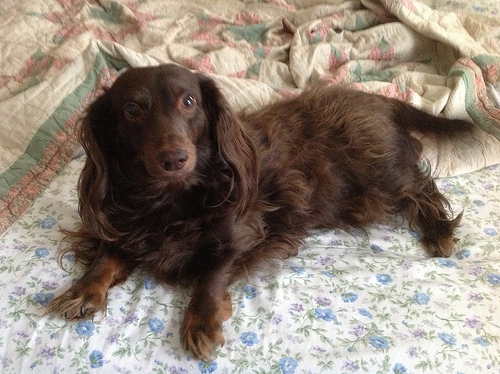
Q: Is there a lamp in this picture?
A: No, there are no lamps.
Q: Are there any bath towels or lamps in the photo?
A: No, there are no lamps or bath towels.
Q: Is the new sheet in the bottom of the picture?
A: Yes, the bed sheet is in the bottom of the image.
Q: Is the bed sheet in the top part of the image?
A: No, the bed sheet is in the bottom of the image.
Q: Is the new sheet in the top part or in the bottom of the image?
A: The sheet is in the bottom of the image.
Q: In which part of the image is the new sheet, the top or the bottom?
A: The sheet is in the bottom of the image.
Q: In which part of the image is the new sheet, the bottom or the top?
A: The sheet is in the bottom of the image.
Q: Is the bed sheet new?
A: Yes, the bed sheet is new.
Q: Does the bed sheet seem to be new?
A: Yes, the bed sheet is new.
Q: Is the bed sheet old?
A: No, the bed sheet is new.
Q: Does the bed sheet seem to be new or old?
A: The bed sheet is new.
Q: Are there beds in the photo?
A: Yes, there is a bed.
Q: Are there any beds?
A: Yes, there is a bed.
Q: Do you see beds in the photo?
A: Yes, there is a bed.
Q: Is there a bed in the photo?
A: Yes, there is a bed.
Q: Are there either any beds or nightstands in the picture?
A: Yes, there is a bed.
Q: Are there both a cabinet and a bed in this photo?
A: No, there is a bed but no cabinets.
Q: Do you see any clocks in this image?
A: No, there are no clocks.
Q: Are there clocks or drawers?
A: No, there are no clocks or drawers.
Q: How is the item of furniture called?
A: The piece of furniture is a bed.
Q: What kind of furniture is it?
A: The piece of furniture is a bed.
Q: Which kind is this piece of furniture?
A: This is a bed.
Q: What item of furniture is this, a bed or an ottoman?
A: This is a bed.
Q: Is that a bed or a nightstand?
A: That is a bed.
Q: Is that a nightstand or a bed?
A: That is a bed.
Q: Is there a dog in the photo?
A: Yes, there is a dog.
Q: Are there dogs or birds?
A: Yes, there is a dog.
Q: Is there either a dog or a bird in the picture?
A: Yes, there is a dog.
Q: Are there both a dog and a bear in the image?
A: No, there is a dog but no bears.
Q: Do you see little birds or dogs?
A: Yes, there is a little dog.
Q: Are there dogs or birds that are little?
A: Yes, the dog is little.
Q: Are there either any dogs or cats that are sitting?
A: Yes, the dog is sitting.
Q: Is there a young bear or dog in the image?
A: Yes, there is a young dog.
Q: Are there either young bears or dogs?
A: Yes, there is a young dog.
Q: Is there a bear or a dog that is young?
A: Yes, the dog is young.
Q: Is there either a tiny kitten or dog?
A: Yes, there is a tiny dog.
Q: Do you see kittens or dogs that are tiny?
A: Yes, the dog is tiny.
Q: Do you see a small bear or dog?
A: Yes, there is a small dog.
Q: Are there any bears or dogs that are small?
A: Yes, the dog is small.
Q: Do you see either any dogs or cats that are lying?
A: Yes, the dog is lying.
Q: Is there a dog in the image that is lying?
A: Yes, there is a dog that is lying.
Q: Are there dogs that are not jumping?
A: Yes, there is a dog that is lying.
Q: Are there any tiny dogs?
A: Yes, there is a tiny dog.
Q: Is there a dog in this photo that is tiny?
A: Yes, there is a dog that is tiny.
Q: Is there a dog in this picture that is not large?
A: Yes, there is a tiny dog.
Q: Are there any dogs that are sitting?
A: Yes, there is a dog that is sitting.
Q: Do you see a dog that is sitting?
A: Yes, there is a dog that is sitting.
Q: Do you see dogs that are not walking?
A: Yes, there is a dog that is sitting .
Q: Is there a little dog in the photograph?
A: Yes, there is a little dog.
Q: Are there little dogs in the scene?
A: Yes, there is a little dog.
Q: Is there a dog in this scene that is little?
A: Yes, there is a dog that is little.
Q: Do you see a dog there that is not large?
A: Yes, there is a little dog.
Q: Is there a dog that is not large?
A: Yes, there is a little dog.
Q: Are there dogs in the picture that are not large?
A: Yes, there is a little dog.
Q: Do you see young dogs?
A: Yes, there is a young dog.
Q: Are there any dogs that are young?
A: Yes, there is a dog that is young.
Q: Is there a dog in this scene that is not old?
A: Yes, there is an young dog.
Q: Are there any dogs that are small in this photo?
A: Yes, there is a small dog.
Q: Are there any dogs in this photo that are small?
A: Yes, there is a dog that is small.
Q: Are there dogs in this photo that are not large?
A: Yes, there is a small dog.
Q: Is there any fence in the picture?
A: No, there are no fences.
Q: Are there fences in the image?
A: No, there are no fences.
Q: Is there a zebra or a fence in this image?
A: No, there are no fences or zebras.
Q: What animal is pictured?
A: The animal is a dog.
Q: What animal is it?
A: The animal is a dog.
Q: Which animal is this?
A: This is a dog.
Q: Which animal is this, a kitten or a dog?
A: This is a dog.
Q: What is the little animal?
A: The animal is a dog.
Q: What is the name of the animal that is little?
A: The animal is a dog.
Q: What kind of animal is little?
A: The animal is a dog.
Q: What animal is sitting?
A: The animal is a dog.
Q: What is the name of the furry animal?
A: The animal is a dog.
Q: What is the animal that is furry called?
A: The animal is a dog.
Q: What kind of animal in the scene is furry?
A: The animal is a dog.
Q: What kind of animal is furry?
A: The animal is a dog.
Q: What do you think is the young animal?
A: The animal is a dog.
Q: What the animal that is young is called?
A: The animal is a dog.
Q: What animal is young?
A: The animal is a dog.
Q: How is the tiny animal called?
A: The animal is a dog.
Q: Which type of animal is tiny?
A: The animal is a dog.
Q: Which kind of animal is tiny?
A: The animal is a dog.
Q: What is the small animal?
A: The animal is a dog.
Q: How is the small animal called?
A: The animal is a dog.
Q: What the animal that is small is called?
A: The animal is a dog.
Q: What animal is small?
A: The animal is a dog.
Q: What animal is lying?
A: The animal is a dog.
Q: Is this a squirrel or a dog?
A: This is a dog.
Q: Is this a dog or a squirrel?
A: This is a dog.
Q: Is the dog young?
A: Yes, the dog is young.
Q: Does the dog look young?
A: Yes, the dog is young.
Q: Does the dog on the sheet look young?
A: Yes, the dog is young.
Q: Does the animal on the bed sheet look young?
A: Yes, the dog is young.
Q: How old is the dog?
A: The dog is young.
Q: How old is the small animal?
A: The dog is young.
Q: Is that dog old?
A: No, the dog is young.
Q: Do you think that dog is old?
A: No, the dog is young.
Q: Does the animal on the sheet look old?
A: No, the dog is young.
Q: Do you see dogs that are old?
A: No, there is a dog but it is young.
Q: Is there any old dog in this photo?
A: No, there is a dog but it is young.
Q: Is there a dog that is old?
A: No, there is a dog but it is young.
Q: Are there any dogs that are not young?
A: No, there is a dog but it is young.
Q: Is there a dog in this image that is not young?
A: No, there is a dog but it is young.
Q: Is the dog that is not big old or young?
A: The dog is young.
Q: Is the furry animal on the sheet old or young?
A: The dog is young.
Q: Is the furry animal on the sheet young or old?
A: The dog is young.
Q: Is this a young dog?
A: Yes, this is a young dog.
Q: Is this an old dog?
A: No, this is a young dog.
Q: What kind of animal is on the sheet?
A: The animal is a dog.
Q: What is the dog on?
A: The dog is on the sheet.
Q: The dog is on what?
A: The dog is on the sheet.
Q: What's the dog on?
A: The dog is on the sheet.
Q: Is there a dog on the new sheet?
A: Yes, there is a dog on the sheet.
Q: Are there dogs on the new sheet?
A: Yes, there is a dog on the sheet.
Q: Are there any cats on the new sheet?
A: No, there is a dog on the bed sheet.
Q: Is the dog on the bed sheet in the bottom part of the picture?
A: Yes, the dog is on the sheet.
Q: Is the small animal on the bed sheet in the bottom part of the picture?
A: Yes, the dog is on the sheet.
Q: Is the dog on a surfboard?
A: No, the dog is on the sheet.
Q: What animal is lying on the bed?
A: The animal is a dog.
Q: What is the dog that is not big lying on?
A: The dog is lying on the bed.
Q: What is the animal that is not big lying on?
A: The dog is lying on the bed.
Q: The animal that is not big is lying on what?
A: The dog is lying on the bed.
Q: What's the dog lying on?
A: The dog is lying on the bed.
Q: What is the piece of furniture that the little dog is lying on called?
A: The piece of furniture is a bed.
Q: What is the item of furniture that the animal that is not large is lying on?
A: The piece of furniture is a bed.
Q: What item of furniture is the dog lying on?
A: The dog is lying on the bed.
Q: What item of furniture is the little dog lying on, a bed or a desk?
A: The dog is lying on a bed.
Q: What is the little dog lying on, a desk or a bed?
A: The dog is lying on a bed.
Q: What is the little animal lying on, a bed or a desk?
A: The dog is lying on a bed.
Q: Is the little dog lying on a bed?
A: Yes, the dog is lying on a bed.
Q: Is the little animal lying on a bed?
A: Yes, the dog is lying on a bed.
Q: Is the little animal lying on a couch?
A: No, the dog is lying on a bed.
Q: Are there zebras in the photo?
A: No, there are no zebras.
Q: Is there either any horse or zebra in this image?
A: No, there are no zebras or horses.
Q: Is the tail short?
A: Yes, the tail is short.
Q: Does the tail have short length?
A: Yes, the tail is short.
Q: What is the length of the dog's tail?
A: The tail is short.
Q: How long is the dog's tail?
A: The tail is short.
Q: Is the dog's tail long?
A: No, the tail is short.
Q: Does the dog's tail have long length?
A: No, the tail is short.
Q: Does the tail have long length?
A: No, the tail is short.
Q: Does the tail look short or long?
A: The tail is short.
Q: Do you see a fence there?
A: No, there are no fences.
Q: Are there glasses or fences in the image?
A: No, there are no fences or glasses.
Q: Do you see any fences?
A: No, there are no fences.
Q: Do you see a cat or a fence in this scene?
A: No, there are no fences or cats.